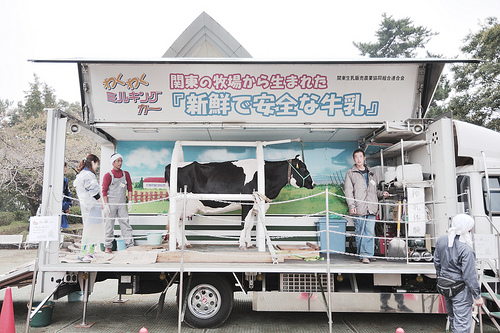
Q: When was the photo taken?
A: During daytime.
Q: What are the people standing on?
A: Platform.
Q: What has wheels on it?
A: The car.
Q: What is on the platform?
A: Chain link rope.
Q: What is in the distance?
A: Trees.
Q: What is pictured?
A: A truck with a cow.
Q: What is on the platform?
A: A cow.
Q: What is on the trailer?
A: A cow.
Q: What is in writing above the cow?
A: Japanese.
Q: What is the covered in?
A: Black spots.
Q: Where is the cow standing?
A: Inside the truck.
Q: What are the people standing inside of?
A: A truck.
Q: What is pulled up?
A: The side wall of the truck.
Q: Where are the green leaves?
A: Behind truck.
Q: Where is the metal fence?
A: Near cow.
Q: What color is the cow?
A: Black and white.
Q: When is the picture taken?
A: Daytime.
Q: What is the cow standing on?
A: A truck.